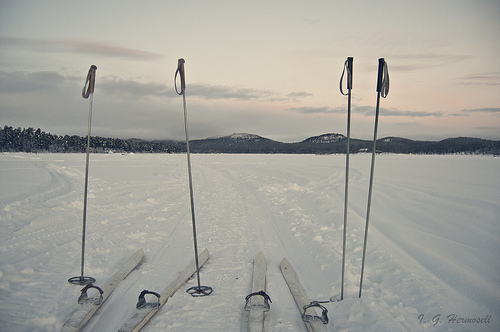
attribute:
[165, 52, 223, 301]
pole — black, standing, long, second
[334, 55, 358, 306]
pole — silver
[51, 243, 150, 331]
ski — first, lying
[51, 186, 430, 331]
snow — white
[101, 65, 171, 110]
cloud — gray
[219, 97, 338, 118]
cloud — pink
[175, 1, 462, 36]
part — sky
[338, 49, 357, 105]
hooker — gray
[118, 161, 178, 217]
part — snow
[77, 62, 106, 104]
belt — gray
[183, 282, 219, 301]
bottom — hooker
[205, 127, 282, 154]
part — mountain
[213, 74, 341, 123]
part — clouds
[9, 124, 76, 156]
part — forest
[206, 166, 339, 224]
surface — white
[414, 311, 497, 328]
name — faint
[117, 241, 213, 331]
ski — second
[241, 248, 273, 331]
ski — third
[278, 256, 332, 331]
ski — last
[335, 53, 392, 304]
poles — standing, next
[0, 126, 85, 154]
trees — heavy, evergreen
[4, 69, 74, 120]
clouds — gray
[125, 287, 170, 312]
binder — black